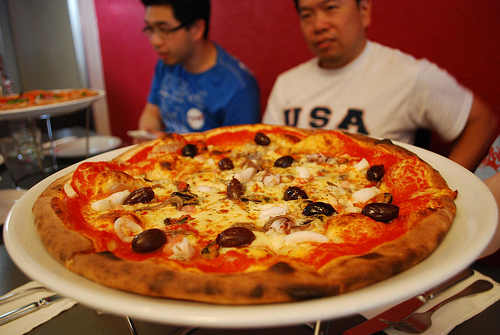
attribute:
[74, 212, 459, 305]
crust — brown, golden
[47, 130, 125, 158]
plate — white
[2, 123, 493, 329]
tray — white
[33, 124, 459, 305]
pizza — round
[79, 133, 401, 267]
cheese — melted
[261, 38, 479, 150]
shirt — white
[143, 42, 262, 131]
shirt — blue, white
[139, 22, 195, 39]
glasses — black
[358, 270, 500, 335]
napkin — white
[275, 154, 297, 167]
olive — black, whole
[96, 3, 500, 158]
wall — red